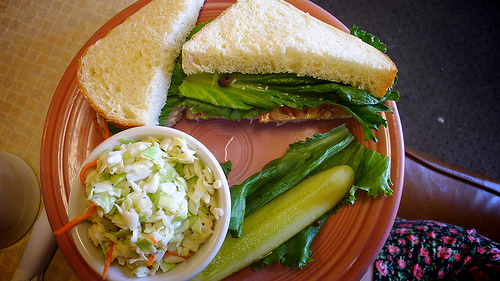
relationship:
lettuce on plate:
[220, 121, 397, 271] [11, 98, 107, 169]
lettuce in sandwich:
[294, 118, 370, 171] [59, 4, 201, 132]